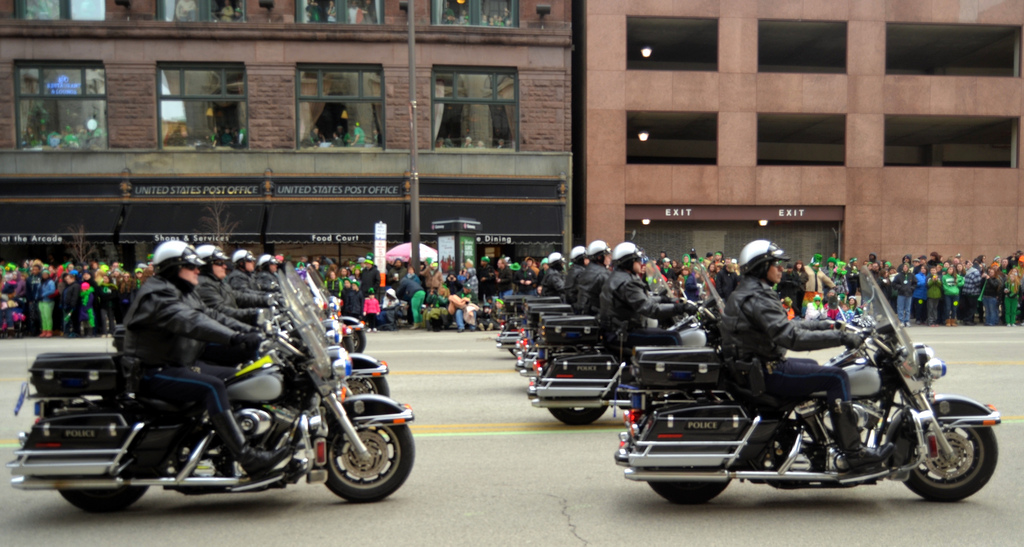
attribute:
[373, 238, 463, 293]
umbrella — pink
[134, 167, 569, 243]
sign — united states post office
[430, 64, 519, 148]
window — brick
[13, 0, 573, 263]
building — brown